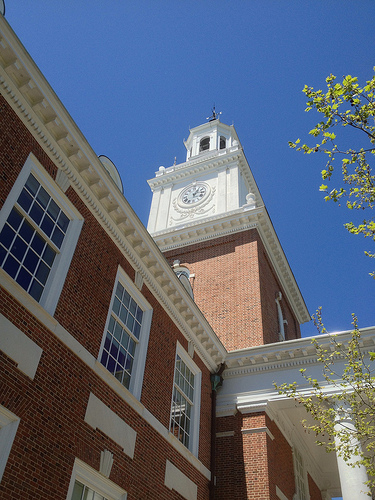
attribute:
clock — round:
[180, 184, 207, 205]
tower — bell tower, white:
[145, 105, 314, 353]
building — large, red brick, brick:
[1, 2, 373, 500]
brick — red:
[249, 448, 255, 451]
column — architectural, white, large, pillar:
[324, 393, 372, 500]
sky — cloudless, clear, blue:
[4, 2, 374, 340]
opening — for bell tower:
[199, 136, 211, 154]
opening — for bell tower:
[219, 136, 227, 151]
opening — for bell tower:
[190, 147, 193, 157]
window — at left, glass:
[1, 150, 87, 319]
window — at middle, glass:
[95, 263, 154, 404]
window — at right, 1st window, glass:
[166, 337, 203, 461]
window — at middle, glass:
[64, 455, 129, 499]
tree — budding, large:
[285, 68, 374, 498]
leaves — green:
[333, 70, 363, 106]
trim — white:
[147, 204, 314, 328]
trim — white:
[1, 1, 374, 379]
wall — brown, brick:
[1, 92, 216, 498]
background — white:
[175, 179, 214, 211]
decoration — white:
[239, 425, 275, 443]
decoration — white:
[133, 269, 147, 293]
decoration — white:
[184, 341, 200, 358]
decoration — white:
[97, 449, 117, 479]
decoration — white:
[243, 188, 259, 211]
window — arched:
[273, 298, 287, 343]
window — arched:
[171, 265, 192, 279]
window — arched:
[96, 153, 125, 197]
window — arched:
[175, 273, 195, 302]